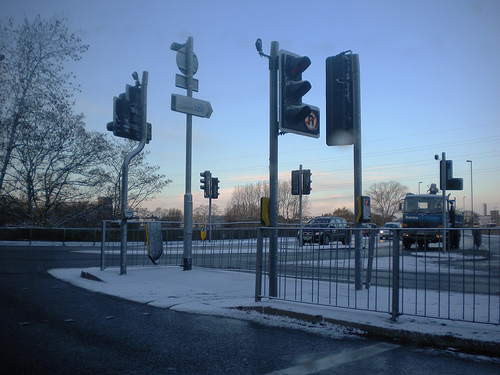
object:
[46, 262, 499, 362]
snow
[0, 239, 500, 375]
ground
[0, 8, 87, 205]
tree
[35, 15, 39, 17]
leaf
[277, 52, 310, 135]
streetlight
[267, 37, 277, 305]
pole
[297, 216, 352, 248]
car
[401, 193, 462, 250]
truck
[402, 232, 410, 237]
light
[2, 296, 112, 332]
walkway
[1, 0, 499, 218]
sky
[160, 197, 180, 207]
cloud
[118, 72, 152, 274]
pole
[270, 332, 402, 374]
line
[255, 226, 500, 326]
railing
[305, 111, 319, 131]
circle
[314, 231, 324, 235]
headlight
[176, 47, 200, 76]
sign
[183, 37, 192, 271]
pole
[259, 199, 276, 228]
traffic sign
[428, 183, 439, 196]
equipment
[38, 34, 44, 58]
branch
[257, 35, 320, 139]
traffic signals